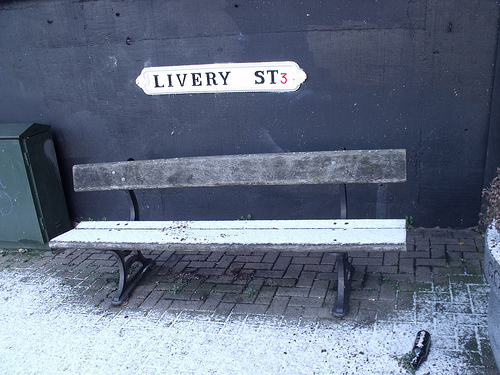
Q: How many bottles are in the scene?
A: 1.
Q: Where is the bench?
A: On a brick sidewalk.